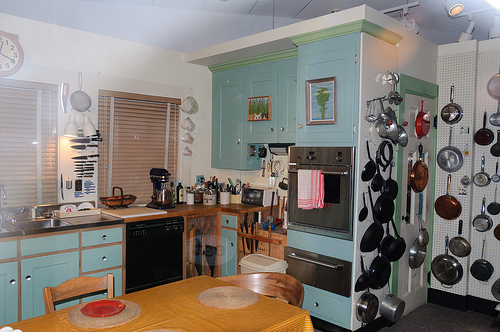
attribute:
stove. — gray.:
[291, 146, 354, 238]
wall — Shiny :
[60, 78, 101, 206]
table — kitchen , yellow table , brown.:
[12, 275, 322, 331]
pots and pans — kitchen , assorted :
[359, 70, 499, 325]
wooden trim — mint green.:
[400, 74, 440, 100]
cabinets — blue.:
[211, 67, 294, 171]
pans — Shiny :
[431, 43, 500, 286]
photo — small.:
[3, 6, 498, 331]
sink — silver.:
[0, 209, 65, 235]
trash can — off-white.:
[242, 255, 289, 274]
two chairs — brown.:
[38, 271, 312, 302]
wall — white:
[365, 41, 475, 78]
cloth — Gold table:
[14, 268, 314, 330]